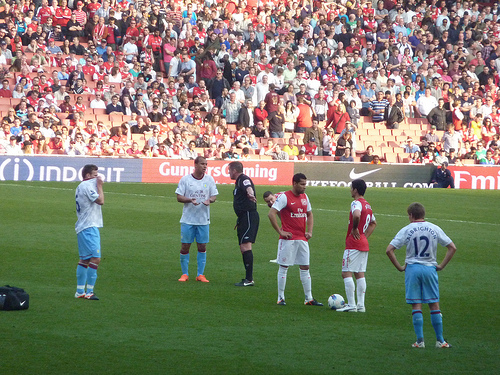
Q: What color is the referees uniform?
A: Black.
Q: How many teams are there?
A: Two.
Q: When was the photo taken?
A: Daytime.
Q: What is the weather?
A: Sunny.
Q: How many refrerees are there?
A: One.